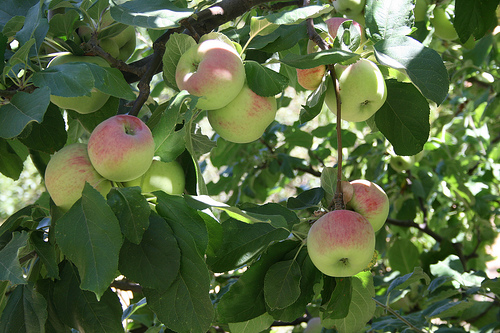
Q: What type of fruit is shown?
A: Apples.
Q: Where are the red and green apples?
A: On a tree.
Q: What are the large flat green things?
A: Leaves.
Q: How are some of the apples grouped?
A: In sets of two.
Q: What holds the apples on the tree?
A: Thick brown branches.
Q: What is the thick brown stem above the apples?
A: A tree limb.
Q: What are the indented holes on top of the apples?
A: Stem hole.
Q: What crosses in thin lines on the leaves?
A: Veins.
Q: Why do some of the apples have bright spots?
A: The sun is shining on them.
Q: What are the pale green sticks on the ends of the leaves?
A: Stems.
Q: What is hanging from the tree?
A: Fruit.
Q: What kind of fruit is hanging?
A: Red and green apples.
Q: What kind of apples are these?
A: Red and green.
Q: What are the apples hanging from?
A: Branches.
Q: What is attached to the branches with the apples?
A: Leaves.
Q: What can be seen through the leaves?
A: Sunlight.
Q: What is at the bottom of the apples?
A: Brown spots.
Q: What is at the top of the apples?
A: Stem.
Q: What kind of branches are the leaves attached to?
A: Brown.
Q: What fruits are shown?
A: Apples.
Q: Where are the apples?
A: On the tree.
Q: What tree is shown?
A: Apple tree.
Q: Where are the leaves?
A: Around the apple.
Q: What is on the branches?
A: Leaves.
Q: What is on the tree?
A: Apples.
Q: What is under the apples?
A: Leaves.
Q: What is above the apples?
A: Branches.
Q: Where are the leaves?
A: On the twigs.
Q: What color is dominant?
A: Green.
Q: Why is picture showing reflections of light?
A: Sun rays.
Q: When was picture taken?
A: Daytime.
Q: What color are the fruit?
A: Red and lime.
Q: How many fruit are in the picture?
A: Seven.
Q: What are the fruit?
A: Probably apples.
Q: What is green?
A: Leaves.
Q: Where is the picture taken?
A: In an apple tree.